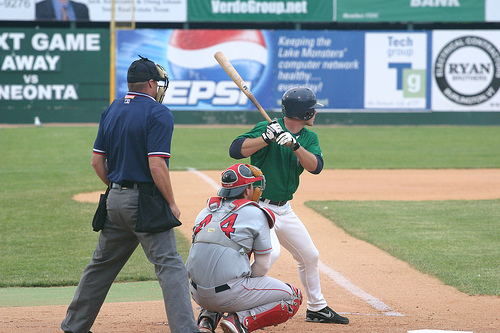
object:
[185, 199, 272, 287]
shirt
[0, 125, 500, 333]
baseball field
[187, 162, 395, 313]
white line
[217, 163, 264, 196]
cap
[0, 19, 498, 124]
wall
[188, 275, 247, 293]
belt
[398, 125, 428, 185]
ground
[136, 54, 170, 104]
face mask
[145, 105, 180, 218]
arm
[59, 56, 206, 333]
guard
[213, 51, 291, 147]
bat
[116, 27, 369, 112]
advertisement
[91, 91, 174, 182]
shirt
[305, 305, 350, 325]
cleat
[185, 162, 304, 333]
catcher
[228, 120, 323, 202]
green shirt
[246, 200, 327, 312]
pants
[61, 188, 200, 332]
pants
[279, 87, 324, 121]
helmet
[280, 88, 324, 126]
head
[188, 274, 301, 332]
pants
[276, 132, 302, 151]
hand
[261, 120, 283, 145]
hand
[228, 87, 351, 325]
batter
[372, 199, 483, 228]
grass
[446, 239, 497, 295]
grass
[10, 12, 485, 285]
game